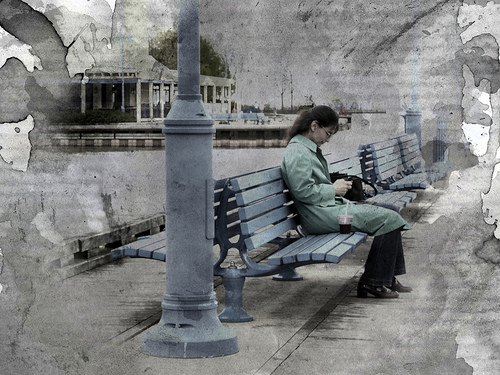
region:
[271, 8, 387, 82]
this is the wall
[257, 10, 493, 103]
the wall is eroded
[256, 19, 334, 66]
the wall is grey in color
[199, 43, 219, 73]
this is some algae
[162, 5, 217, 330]
this is a pole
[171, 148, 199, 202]
the pole is grey in color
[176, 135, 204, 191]
the pole is made of concrete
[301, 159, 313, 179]
this is a rain coat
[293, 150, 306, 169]
the coat is green in color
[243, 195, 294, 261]
this is a bench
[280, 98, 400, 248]
a woman looking at her cell phone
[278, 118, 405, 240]
a woman in a long green coat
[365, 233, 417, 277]
a person wearing black pants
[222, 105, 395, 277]
a woman sitting on a bench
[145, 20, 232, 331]
a metal light pole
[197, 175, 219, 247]
electrical access panel on a pole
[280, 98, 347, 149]
a woman with long hair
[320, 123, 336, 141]
a person wearing eyeglasses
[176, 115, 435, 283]
a row of outdoor benches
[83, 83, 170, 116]
exterior pillars on a building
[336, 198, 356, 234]
a drink cup next to a woman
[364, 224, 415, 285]
black pants on a woman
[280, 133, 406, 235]
a pale green coat on a woman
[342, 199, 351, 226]
a straw in a cup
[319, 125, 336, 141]
glasses on a woman's face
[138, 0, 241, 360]
a post next to a bench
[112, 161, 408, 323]
a green double sided bench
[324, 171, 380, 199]
a black bag next to a woman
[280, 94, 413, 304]
a woman seated on a bench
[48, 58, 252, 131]
a building in the background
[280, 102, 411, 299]
A woman sitting down.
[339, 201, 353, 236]
A drink in a clear cup.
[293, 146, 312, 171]
Part of the green jacket.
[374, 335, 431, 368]
Part of the street.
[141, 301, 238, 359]
The bottom of a metal post.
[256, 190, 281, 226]
Part of the bench.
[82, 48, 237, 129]
A building in the background.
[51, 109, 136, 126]
A small green bush.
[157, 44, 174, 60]
part of a green tree.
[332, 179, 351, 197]
The woman's hand.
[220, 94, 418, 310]
a woman sits on a bench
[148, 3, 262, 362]
a gray pole on side a bench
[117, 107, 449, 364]
benches on side a pole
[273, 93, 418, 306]
woman wears a green coat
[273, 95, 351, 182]
woman combs with a pony tail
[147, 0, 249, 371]
a pole color gray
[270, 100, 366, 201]
woman is looking down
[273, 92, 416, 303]
woman wears a long green coat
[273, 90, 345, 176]
woman uses glasses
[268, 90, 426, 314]
woman wears black pants